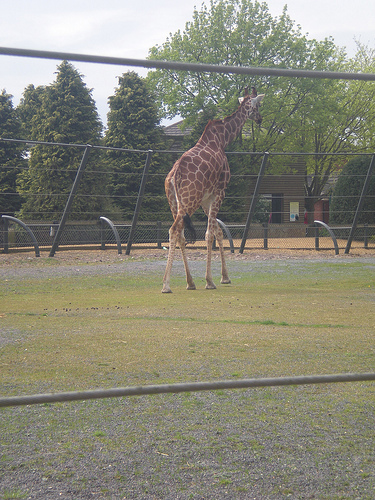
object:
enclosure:
[0, 138, 375, 496]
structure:
[16, 210, 361, 251]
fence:
[0, 137, 375, 254]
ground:
[234, 236, 332, 248]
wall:
[310, 220, 355, 238]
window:
[257, 193, 282, 224]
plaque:
[288, 178, 300, 201]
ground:
[55, 392, 350, 498]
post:
[118, 376, 220, 401]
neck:
[199, 98, 246, 147]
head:
[237, 86, 264, 126]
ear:
[252, 91, 270, 106]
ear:
[236, 94, 244, 104]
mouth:
[251, 111, 263, 129]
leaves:
[48, 86, 79, 135]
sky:
[68, 11, 132, 38]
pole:
[42, 47, 332, 82]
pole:
[97, 210, 123, 257]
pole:
[0, 211, 40, 259]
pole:
[64, 143, 128, 215]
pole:
[238, 154, 267, 256]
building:
[158, 102, 330, 243]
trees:
[0, 83, 27, 233]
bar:
[89, 53, 315, 79]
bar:
[61, 374, 315, 403]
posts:
[1, 138, 87, 147]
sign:
[289, 201, 299, 225]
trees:
[104, 70, 171, 218]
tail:
[170, 173, 196, 250]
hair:
[182, 214, 196, 243]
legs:
[216, 215, 226, 276]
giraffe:
[157, 88, 265, 291]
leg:
[205, 205, 214, 270]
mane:
[199, 98, 247, 138]